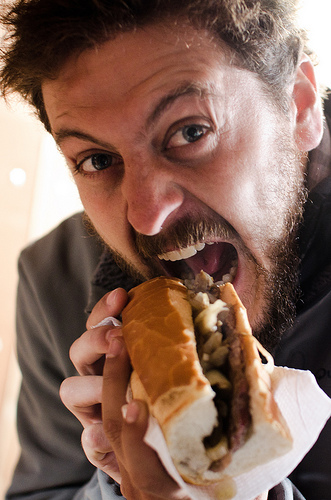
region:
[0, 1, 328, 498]
"He is going to eat a sandwich"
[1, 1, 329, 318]
"He has his mouth opened"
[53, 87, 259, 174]
"A picture of a guy's eyes"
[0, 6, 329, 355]
"He has a beard and mustache"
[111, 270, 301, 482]
"A sandwich is pictured here"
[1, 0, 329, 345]
"The man has dark hair"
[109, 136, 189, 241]
"A man's nose"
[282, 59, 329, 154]
"An ear is pictured here"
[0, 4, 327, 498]
"He is wearing long sleeves"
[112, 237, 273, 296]
"Mouth and teeth"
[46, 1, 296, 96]
man has dark hair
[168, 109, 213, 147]
man has grey eyes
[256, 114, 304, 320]
man has facial hair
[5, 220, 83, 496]
man has grey jacket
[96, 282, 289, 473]
man is holding sandwich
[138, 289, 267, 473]
sandwich has white bread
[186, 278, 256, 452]
brown meat in white bread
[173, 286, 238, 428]
vegetables in white bread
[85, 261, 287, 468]
sandwich on white paper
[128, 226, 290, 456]
man is eating sandwich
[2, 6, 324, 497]
a man with brown hair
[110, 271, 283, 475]
philly cheesesteak sandwich in man's hand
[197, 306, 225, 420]
onions on philly cheese steak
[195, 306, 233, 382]
cheese on philly cheese steak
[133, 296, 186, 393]
bun on philly cheesesteak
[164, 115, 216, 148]
blue eye of man with brown hair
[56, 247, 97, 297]
grey jacket on man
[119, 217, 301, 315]
brown beard on man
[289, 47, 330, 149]
ear of man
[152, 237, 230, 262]
white teeth of man with brown hair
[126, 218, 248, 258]
man's brown moustache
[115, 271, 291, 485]
half of a large sandwich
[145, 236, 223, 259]
man's upper teeth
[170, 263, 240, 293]
man's lower teeth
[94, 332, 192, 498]
another person's hand on the sandwich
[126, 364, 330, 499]
white napkin around the sandwich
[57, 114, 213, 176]
eyes looking at the camera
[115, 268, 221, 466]
top part of the bread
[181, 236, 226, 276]
tongue in the man's mouth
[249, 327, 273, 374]
onion falling off the sandwich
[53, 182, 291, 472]
man about to take huge bite of sandwich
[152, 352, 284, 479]
bread roll with meat and onions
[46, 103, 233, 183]
blue eyes and long eyelashes on man's face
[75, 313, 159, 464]
napkin wrapped around a sandwich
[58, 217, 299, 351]
man's brown beard and mustache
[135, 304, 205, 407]
cracked top crust on bread roll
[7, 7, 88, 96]
man's thick brown hair on head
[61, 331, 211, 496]
both hands being used to hold sandwich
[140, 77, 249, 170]
wrinkled skin around eyebrow and eye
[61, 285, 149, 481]
one hand is tanner than the other